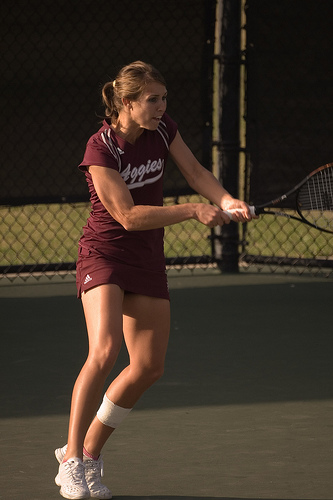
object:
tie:
[111, 78, 118, 89]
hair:
[96, 60, 167, 129]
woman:
[51, 61, 256, 499]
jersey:
[79, 114, 176, 261]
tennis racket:
[220, 163, 333, 234]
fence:
[1, 1, 219, 278]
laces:
[68, 458, 86, 484]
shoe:
[55, 457, 90, 499]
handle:
[221, 204, 260, 221]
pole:
[216, 0, 244, 275]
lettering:
[120, 157, 167, 188]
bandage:
[96, 393, 131, 429]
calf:
[90, 366, 152, 453]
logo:
[83, 272, 93, 286]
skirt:
[74, 243, 171, 302]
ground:
[2, 270, 332, 499]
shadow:
[1, 280, 333, 417]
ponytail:
[92, 77, 119, 125]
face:
[134, 84, 169, 131]